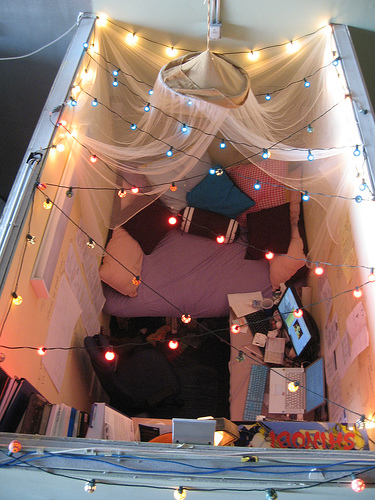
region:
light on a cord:
[268, 366, 321, 392]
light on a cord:
[156, 330, 183, 353]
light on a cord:
[96, 345, 124, 373]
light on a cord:
[25, 336, 46, 362]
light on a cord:
[8, 283, 30, 313]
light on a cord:
[122, 267, 147, 288]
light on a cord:
[311, 257, 327, 284]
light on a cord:
[262, 244, 274, 266]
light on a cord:
[201, 232, 236, 249]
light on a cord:
[155, 209, 187, 231]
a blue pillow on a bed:
[182, 161, 259, 221]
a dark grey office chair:
[82, 331, 191, 414]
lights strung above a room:
[0, 22, 374, 497]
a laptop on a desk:
[264, 354, 328, 419]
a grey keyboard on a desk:
[238, 357, 268, 422]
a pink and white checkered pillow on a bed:
[225, 155, 291, 218]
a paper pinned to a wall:
[343, 299, 373, 362]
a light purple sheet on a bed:
[101, 232, 311, 319]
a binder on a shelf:
[2, 374, 49, 435]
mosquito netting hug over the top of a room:
[39, 19, 373, 241]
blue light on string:
[301, 192, 310, 201]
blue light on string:
[252, 180, 262, 188]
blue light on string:
[210, 165, 214, 172]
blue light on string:
[166, 147, 172, 157]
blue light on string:
[132, 121, 136, 131]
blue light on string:
[91, 98, 96, 106]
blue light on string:
[307, 149, 317, 162]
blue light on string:
[260, 149, 270, 159]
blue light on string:
[264, 93, 274, 102]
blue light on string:
[302, 80, 312, 90]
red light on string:
[350, 475, 368, 495]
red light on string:
[6, 440, 24, 461]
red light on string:
[32, 348, 50, 360]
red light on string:
[102, 349, 115, 362]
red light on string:
[167, 338, 177, 351]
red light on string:
[131, 276, 143, 287]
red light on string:
[182, 314, 192, 323]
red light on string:
[231, 321, 239, 338]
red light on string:
[218, 234, 222, 245]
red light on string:
[167, 217, 179, 224]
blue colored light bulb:
[352, 194, 364, 203]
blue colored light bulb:
[300, 195, 309, 203]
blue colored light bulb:
[252, 183, 261, 190]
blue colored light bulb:
[207, 168, 218, 175]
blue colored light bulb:
[167, 151, 172, 155]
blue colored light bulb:
[129, 123, 136, 129]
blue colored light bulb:
[91, 100, 97, 106]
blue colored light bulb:
[70, 99, 75, 105]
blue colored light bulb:
[302, 82, 310, 87]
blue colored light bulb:
[264, 93, 272, 100]